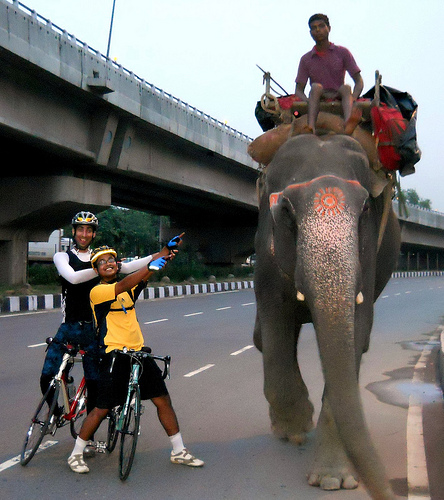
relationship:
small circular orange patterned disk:
[323, 189, 342, 253] [316, 186, 348, 219]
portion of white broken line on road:
[165, 292, 223, 389] [170, 242, 237, 376]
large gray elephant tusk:
[278, 299, 385, 500] [281, 265, 360, 500]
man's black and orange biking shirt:
[64, 229, 205, 475] [95, 299, 149, 388]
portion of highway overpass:
[156, 149, 223, 223] [137, 131, 232, 195]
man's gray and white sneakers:
[57, 305, 211, 500] [68, 437, 213, 500]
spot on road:
[372, 358, 427, 416] [0, 268, 444, 500]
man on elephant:
[293, 12, 364, 136] [249, 130, 407, 498]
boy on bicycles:
[65, 230, 205, 473] [13, 320, 172, 480]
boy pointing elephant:
[65, 230, 205, 473] [249, 130, 407, 498]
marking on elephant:
[306, 180, 347, 226] [252, 125, 427, 493]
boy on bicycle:
[39, 212, 179, 459] [93, 344, 172, 483]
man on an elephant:
[280, 3, 382, 147] [241, 138, 422, 498]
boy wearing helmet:
[39, 212, 179, 459] [84, 241, 125, 263]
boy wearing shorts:
[65, 230, 205, 473] [87, 347, 175, 411]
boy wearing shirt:
[39, 212, 179, 459] [48, 246, 159, 330]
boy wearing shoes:
[39, 212, 179, 459] [63, 448, 208, 477]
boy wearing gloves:
[65, 230, 205, 473] [139, 229, 187, 276]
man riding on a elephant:
[293, 12, 364, 136] [249, 130, 407, 498]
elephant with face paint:
[249, 130, 407, 498] [300, 184, 362, 271]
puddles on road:
[383, 335, 429, 400] [378, 273, 430, 488]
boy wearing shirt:
[42, 205, 193, 449] [52, 246, 153, 283]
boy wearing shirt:
[39, 212, 179, 459] [87, 280, 145, 354]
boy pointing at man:
[65, 230, 205, 473] [293, 12, 364, 136]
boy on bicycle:
[65, 230, 205, 473] [19, 334, 104, 467]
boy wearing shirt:
[64, 230, 204, 473] [87, 280, 145, 354]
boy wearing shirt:
[64, 230, 204, 473] [88, 279, 148, 359]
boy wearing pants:
[39, 212, 179, 459] [39, 320, 97, 413]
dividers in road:
[141, 297, 255, 326] [12, 268, 426, 494]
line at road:
[402, 342, 430, 498] [12, 268, 426, 494]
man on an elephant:
[293, 12, 364, 136] [249, 130, 407, 498]